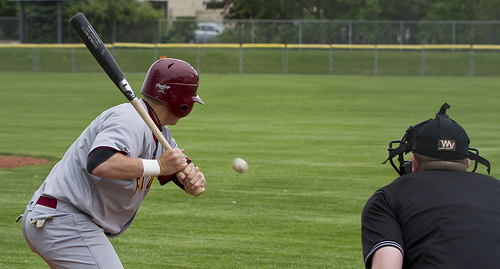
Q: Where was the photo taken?
A: It was taken at the field.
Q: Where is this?
A: This is at the field.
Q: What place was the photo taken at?
A: It was taken at the field.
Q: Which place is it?
A: It is a field.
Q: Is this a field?
A: Yes, it is a field.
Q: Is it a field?
A: Yes, it is a field.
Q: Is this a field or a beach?
A: It is a field.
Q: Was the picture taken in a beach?
A: No, the picture was taken in a field.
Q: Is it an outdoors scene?
A: Yes, it is outdoors.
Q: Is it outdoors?
A: Yes, it is outdoors.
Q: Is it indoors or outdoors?
A: It is outdoors.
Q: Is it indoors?
A: No, it is outdoors.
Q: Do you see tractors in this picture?
A: No, there are no tractors.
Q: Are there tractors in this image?
A: No, there are no tractors.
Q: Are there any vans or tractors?
A: No, there are no tractors or vans.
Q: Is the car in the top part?
A: Yes, the car is in the top of the image.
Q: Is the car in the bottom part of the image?
A: No, the car is in the top of the image.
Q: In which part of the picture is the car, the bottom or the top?
A: The car is in the top of the image.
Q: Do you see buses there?
A: No, there are no buses.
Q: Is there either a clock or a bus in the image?
A: No, there are no buses or clocks.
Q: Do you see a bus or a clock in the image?
A: No, there are no buses or clocks.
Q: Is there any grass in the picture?
A: Yes, there is grass.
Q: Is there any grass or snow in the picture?
A: Yes, there is grass.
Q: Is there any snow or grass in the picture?
A: Yes, there is grass.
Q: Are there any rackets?
A: No, there are no rackets.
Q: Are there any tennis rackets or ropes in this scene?
A: No, there are no tennis rackets or ropes.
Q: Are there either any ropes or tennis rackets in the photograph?
A: No, there are no tennis rackets or ropes.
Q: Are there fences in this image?
A: Yes, there is a fence.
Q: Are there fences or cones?
A: Yes, there is a fence.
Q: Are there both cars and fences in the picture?
A: Yes, there are both a fence and a car.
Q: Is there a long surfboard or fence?
A: Yes, there is a long fence.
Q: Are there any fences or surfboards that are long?
A: Yes, the fence is long.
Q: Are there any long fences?
A: Yes, there is a long fence.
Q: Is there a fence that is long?
A: Yes, there is a fence that is long.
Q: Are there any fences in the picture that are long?
A: Yes, there is a fence that is long.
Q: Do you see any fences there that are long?
A: Yes, there is a fence that is long.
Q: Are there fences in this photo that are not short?
A: Yes, there is a long fence.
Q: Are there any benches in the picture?
A: No, there are no benches.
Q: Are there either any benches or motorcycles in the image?
A: No, there are no benches or motorcycles.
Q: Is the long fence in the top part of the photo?
A: Yes, the fence is in the top of the image.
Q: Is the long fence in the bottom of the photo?
A: No, the fence is in the top of the image.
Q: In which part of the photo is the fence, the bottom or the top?
A: The fence is in the top of the image.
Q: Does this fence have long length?
A: Yes, the fence is long.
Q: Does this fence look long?
A: Yes, the fence is long.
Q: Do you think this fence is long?
A: Yes, the fence is long.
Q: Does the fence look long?
A: Yes, the fence is long.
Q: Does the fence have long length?
A: Yes, the fence is long.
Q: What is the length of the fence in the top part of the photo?
A: The fence is long.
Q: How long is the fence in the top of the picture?
A: The fence is long.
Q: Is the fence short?
A: No, the fence is long.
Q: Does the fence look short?
A: No, the fence is long.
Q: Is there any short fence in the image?
A: No, there is a fence but it is long.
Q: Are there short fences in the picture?
A: No, there is a fence but it is long.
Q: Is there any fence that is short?
A: No, there is a fence but it is long.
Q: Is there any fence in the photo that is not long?
A: No, there is a fence but it is long.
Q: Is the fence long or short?
A: The fence is long.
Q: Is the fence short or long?
A: The fence is long.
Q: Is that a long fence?
A: Yes, that is a long fence.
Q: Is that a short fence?
A: No, that is a long fence.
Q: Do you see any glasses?
A: No, there are no glasses.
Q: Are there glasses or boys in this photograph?
A: No, there are no glasses or boys.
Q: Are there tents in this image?
A: No, there are no tents.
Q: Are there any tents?
A: No, there are no tents.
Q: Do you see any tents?
A: No, there are no tents.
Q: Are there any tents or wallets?
A: No, there are no tents or wallets.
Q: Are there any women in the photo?
A: No, there are no women.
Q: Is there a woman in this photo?
A: No, there are no women.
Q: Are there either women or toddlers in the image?
A: No, there are no women or toddlers.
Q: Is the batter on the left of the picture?
A: Yes, the batter is on the left of the image.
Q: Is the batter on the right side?
A: No, the batter is on the left of the image.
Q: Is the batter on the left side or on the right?
A: The batter is on the left of the image.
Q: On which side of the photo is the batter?
A: The batter is on the left of the image.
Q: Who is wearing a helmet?
A: The batter is wearing a helmet.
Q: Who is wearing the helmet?
A: The batter is wearing a helmet.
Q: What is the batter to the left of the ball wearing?
A: The batter is wearing a helmet.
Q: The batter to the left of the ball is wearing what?
A: The batter is wearing a helmet.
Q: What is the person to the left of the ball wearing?
A: The batter is wearing a helmet.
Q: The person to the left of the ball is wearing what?
A: The batter is wearing a helmet.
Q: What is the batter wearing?
A: The batter is wearing a helmet.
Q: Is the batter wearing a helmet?
A: Yes, the batter is wearing a helmet.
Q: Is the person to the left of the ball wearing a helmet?
A: Yes, the batter is wearing a helmet.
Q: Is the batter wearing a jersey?
A: No, the batter is wearing a helmet.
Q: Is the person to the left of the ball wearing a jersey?
A: No, the batter is wearing a helmet.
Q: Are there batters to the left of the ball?
A: Yes, there is a batter to the left of the ball.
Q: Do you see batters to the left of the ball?
A: Yes, there is a batter to the left of the ball.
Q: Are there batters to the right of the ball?
A: No, the batter is to the left of the ball.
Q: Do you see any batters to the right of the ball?
A: No, the batter is to the left of the ball.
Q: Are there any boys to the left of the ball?
A: No, there is a batter to the left of the ball.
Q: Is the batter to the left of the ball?
A: Yes, the batter is to the left of the ball.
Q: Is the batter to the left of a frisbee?
A: No, the batter is to the left of the ball.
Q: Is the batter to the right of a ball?
A: No, the batter is to the left of a ball.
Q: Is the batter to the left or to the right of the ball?
A: The batter is to the left of the ball.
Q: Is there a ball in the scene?
A: Yes, there is a ball.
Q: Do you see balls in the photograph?
A: Yes, there is a ball.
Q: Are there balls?
A: Yes, there is a ball.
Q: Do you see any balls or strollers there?
A: Yes, there is a ball.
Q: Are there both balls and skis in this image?
A: No, there is a ball but no skis.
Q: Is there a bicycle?
A: No, there are no bicycles.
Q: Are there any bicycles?
A: No, there are no bicycles.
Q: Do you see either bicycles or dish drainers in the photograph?
A: No, there are no bicycles or dish drainers.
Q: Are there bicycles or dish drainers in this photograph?
A: No, there are no bicycles or dish drainers.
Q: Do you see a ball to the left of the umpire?
A: Yes, there is a ball to the left of the umpire.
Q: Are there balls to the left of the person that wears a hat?
A: Yes, there is a ball to the left of the umpire.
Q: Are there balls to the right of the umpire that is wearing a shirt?
A: No, the ball is to the left of the umpire.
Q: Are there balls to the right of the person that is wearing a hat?
A: No, the ball is to the left of the umpire.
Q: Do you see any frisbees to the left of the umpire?
A: No, there is a ball to the left of the umpire.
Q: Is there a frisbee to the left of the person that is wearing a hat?
A: No, there is a ball to the left of the umpire.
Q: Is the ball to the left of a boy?
A: No, the ball is to the left of the umpire.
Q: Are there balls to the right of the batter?
A: Yes, there is a ball to the right of the batter.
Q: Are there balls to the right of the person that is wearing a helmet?
A: Yes, there is a ball to the right of the batter.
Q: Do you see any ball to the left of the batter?
A: No, the ball is to the right of the batter.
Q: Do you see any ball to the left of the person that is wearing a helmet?
A: No, the ball is to the right of the batter.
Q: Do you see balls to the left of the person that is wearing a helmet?
A: No, the ball is to the right of the batter.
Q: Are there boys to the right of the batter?
A: No, there is a ball to the right of the batter.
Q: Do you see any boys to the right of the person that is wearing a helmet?
A: No, there is a ball to the right of the batter.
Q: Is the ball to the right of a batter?
A: Yes, the ball is to the right of a batter.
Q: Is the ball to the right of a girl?
A: No, the ball is to the right of a batter.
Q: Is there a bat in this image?
A: Yes, there is a bat.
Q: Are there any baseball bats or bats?
A: Yes, there is a bat.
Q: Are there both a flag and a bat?
A: No, there is a bat but no flags.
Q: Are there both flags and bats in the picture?
A: No, there is a bat but no flags.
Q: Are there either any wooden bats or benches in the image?
A: Yes, there is a wood bat.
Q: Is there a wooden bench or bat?
A: Yes, there is a wood bat.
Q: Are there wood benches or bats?
A: Yes, there is a wood bat.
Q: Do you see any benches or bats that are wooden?
A: Yes, the bat is wooden.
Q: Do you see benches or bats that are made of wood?
A: Yes, the bat is made of wood.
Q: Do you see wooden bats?
A: Yes, there is a wood bat.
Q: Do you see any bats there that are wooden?
A: Yes, there is a bat that is wooden.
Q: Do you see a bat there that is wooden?
A: Yes, there is a bat that is wooden.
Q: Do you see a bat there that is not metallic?
A: Yes, there is a wooden bat.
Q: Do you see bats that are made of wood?
A: Yes, there is a bat that is made of wood.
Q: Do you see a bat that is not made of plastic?
A: Yes, there is a bat that is made of wood.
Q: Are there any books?
A: No, there are no books.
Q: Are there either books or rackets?
A: No, there are no books or rackets.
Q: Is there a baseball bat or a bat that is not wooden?
A: No, there is a bat but it is wooden.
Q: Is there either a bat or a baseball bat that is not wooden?
A: No, there is a bat but it is wooden.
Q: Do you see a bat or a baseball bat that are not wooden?
A: No, there is a bat but it is wooden.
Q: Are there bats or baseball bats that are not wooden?
A: No, there is a bat but it is wooden.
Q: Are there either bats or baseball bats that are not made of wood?
A: No, there is a bat but it is made of wood.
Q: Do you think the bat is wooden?
A: Yes, the bat is wooden.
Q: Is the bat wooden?
A: Yes, the bat is wooden.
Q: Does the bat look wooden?
A: Yes, the bat is wooden.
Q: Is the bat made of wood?
A: Yes, the bat is made of wood.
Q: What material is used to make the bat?
A: The bat is made of wood.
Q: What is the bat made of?
A: The bat is made of wood.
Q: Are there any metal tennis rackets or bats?
A: No, there is a bat but it is wooden.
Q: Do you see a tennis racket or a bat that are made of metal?
A: No, there is a bat but it is made of wood.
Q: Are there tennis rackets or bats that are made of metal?
A: No, there is a bat but it is made of wood.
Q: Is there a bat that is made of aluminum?
A: No, there is a bat but it is made of wood.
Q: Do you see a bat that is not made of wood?
A: No, there is a bat but it is made of wood.